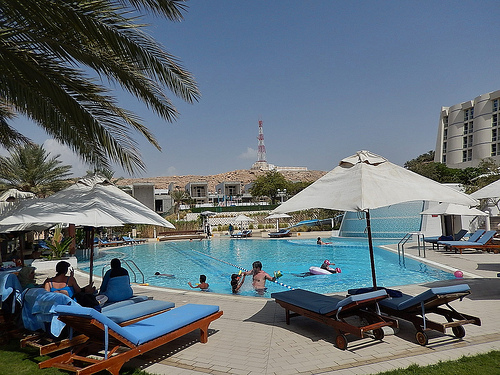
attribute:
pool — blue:
[79, 234, 469, 301]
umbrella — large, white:
[270, 152, 478, 339]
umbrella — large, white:
[0, 177, 175, 297]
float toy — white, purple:
[309, 265, 336, 278]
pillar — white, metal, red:
[252, 114, 271, 173]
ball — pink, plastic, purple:
[455, 270, 464, 280]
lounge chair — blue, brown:
[272, 289, 390, 349]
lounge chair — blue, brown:
[348, 284, 482, 345]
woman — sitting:
[45, 262, 82, 298]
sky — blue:
[1, 0, 499, 182]